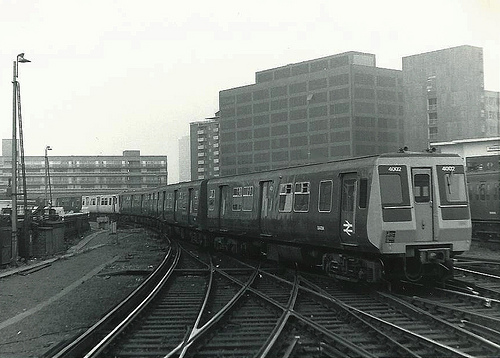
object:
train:
[53, 154, 472, 288]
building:
[402, 44, 500, 153]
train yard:
[0, 221, 500, 357]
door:
[412, 167, 435, 243]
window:
[317, 180, 332, 213]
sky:
[0, 2, 500, 185]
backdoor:
[341, 173, 359, 244]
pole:
[14, 51, 26, 267]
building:
[189, 113, 221, 181]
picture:
[0, 2, 500, 357]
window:
[427, 95, 436, 104]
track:
[42, 228, 500, 358]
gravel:
[0, 224, 169, 357]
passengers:
[278, 179, 312, 213]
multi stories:
[400, 78, 474, 95]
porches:
[429, 97, 436, 106]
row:
[424, 50, 439, 150]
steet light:
[12, 52, 30, 269]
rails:
[52, 234, 182, 356]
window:
[328, 73, 351, 85]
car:
[206, 151, 473, 287]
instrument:
[16, 53, 31, 63]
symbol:
[421, 218, 427, 230]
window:
[377, 175, 405, 206]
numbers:
[388, 165, 403, 171]